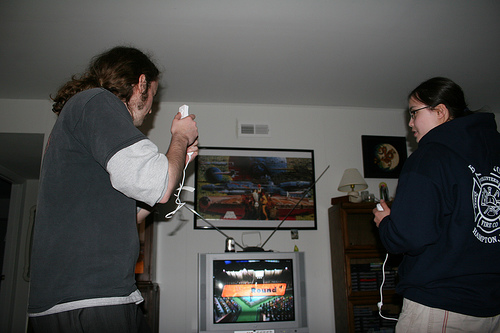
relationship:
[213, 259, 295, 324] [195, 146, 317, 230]
game below picture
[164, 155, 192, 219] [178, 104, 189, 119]
wire on controller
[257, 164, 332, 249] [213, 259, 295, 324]
aentenna on game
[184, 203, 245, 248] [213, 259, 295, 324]
aentenna on game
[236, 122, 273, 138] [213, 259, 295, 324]
vent above game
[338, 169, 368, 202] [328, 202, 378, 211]
lamp on shelf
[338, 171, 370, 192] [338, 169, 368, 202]
shade of lamp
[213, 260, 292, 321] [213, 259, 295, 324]
game on game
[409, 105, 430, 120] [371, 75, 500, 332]
glasses on woman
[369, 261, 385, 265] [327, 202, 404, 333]
cd in bookcase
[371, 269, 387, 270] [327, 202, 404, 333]
cd in bookcase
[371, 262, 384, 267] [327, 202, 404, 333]
cd in bookcase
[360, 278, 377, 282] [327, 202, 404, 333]
cd in bookcase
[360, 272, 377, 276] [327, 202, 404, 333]
cd in bookcase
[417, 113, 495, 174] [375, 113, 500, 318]
hood of sweater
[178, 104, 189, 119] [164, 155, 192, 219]
controller has a wire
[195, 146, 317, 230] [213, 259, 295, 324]
picture above game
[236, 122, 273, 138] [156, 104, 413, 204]
vent on wall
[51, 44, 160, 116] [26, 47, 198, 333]
hair on man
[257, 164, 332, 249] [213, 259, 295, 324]
aentenna ont he game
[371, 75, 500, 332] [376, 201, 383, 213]
woman holding controller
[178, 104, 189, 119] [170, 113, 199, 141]
controller in hand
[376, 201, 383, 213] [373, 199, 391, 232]
controller in hand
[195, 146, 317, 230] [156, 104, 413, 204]
picture on wall